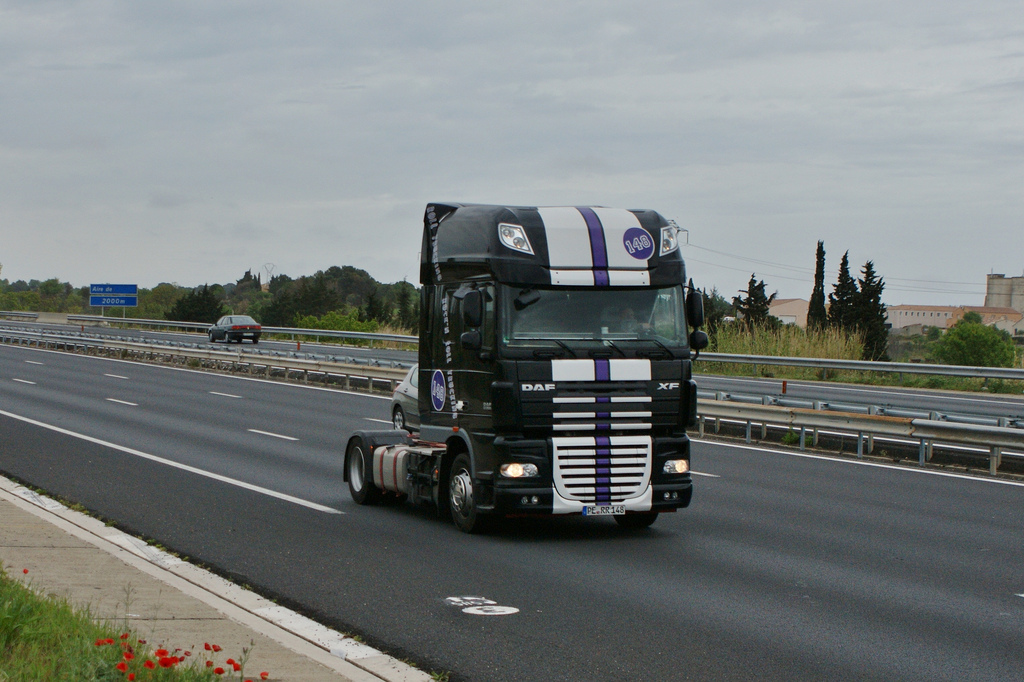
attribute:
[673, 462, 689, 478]
light — white 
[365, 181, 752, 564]
truck — black, white, purple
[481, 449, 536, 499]
light — white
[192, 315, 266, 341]
car — black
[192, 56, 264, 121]
clouds — white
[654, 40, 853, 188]
sky — blue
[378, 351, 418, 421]
vehicle — silver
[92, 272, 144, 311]
sign — blue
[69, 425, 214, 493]
line — white, solid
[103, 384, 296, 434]
lines — broken, white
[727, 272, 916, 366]
field — small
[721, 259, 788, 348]
tree — small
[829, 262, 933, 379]
tree — small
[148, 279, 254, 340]
tree — small, growing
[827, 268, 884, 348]
leaves — green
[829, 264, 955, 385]
leaves — green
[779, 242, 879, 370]
leaves — green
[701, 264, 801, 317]
leaves — green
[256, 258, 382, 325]
tree — green